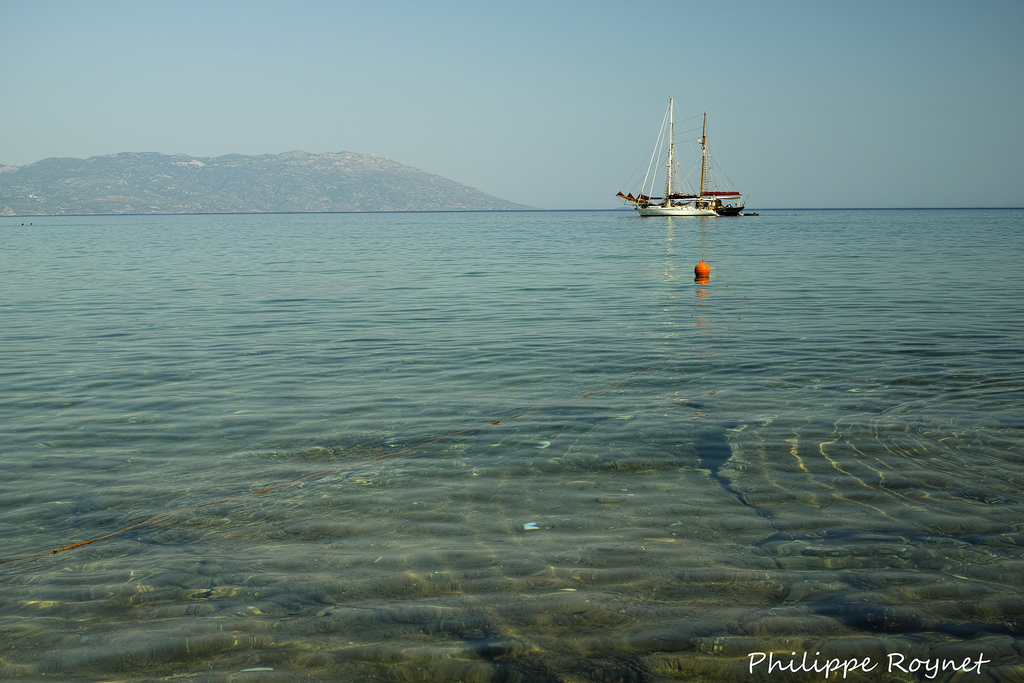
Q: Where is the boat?
A: In the water.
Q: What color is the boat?
A: White.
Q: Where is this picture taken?
A: The ocean.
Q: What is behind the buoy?
A: A boat.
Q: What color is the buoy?
A: Red.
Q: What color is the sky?
A: Blue.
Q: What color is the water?
A: Green.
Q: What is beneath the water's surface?
A: Rocks.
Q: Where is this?
A: Ocean.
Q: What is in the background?
A: Ship.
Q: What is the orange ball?
A: Weather balloon.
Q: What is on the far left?
A: Island.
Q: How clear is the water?
A: Very clear g.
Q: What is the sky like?
A: Clear.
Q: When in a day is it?
A: Afternoon.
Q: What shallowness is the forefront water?
A: Very shallow.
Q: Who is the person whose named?
A: Photographer.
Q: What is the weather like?
A: Clear.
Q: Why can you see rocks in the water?
A: Shallow.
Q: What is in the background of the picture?
A: Mountain.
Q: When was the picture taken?
A: Sunny day.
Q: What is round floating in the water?
A: Red buoy.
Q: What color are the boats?
A: Black and white.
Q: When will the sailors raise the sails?
A: When the wind picks up.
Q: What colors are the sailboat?
A: White and brown.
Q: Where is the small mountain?
A: By the end of the ocean.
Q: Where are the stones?
A: Under the water.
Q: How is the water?
A: Clear.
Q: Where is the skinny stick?
A: On the water.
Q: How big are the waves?
A: Very small.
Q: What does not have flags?
A: The sailboat.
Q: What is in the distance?
A: A hill.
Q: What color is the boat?
A: White.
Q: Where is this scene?
A: Ocean.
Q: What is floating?
A: Boat.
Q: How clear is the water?
A: Very clear.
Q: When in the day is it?
A: Afternoon.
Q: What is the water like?
A: Smooth.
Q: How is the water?
A: The water is murky.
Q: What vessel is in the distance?
A: A ship is in the distance.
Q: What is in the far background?
A: A mountain.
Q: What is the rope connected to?
A: An orange buoy.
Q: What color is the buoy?
A: Orange.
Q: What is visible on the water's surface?
A: Ripples.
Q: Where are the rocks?
A: Below the water's surface.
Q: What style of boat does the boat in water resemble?
A: Sailboat.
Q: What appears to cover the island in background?
A: Vegetation.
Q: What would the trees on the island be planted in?
A: Soil.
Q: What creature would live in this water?
A: Fish.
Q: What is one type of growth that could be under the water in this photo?
A: Seaweed.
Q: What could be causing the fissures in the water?
A: Rocks under surface.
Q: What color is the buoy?
A: Orange.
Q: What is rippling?
A: The water.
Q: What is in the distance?
A: A boat.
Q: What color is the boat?
A: White.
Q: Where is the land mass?
A: To the left.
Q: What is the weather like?
A: Overcast.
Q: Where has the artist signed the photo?
A: On the bottom right.